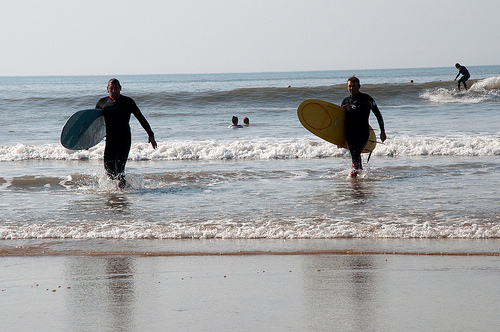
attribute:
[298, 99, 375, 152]
surfboard — yellow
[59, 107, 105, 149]
surfboard — blue 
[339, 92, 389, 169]
wetsuit — black 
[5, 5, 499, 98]
sky — hazy , grey 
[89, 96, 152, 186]
wetsuit — black 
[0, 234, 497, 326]
sand — wet 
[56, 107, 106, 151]
board — blue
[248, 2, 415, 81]
sky — gray 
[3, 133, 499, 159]
wave — white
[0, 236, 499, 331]
shoreline — wet, sandy